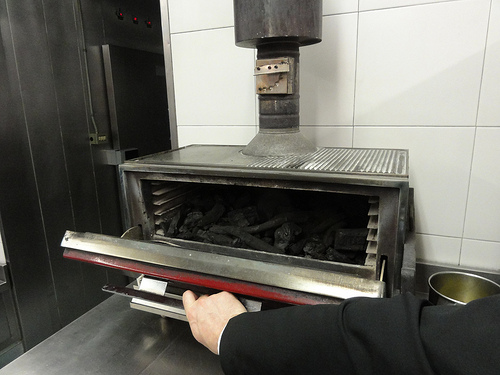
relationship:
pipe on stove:
[233, 2, 322, 157] [61, 143, 414, 323]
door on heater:
[58, 217, 383, 323] [58, 142, 413, 337]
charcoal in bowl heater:
[163, 200, 365, 273] [60, 0, 414, 335]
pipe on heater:
[233, 2, 322, 157] [232, 4, 357, 144]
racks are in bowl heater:
[365, 201, 377, 268] [60, 0, 414, 335]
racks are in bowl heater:
[150, 185, 182, 227] [60, 0, 414, 335]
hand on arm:
[180, 287, 252, 363] [174, 279, 355, 367]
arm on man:
[174, 279, 355, 367] [163, 269, 495, 369]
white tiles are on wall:
[170, 16, 482, 168] [177, 10, 493, 173]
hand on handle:
[174, 274, 274, 363] [120, 273, 264, 338]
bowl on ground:
[426, 270, 498, 304] [118, 313, 158, 364]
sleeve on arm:
[217, 292, 497, 374] [218, 293, 499, 373]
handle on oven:
[101, 279, 261, 325] [57, 142, 419, 336]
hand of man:
[180, 287, 252, 363] [214, 285, 497, 373]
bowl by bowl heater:
[426, 270, 498, 304] [274, 161, 490, 309]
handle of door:
[98, 279, 185, 334] [71, 217, 377, 312]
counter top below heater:
[0, 278, 431, 373] [58, 142, 413, 337]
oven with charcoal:
[57, 142, 419, 336] [216, 210, 306, 234]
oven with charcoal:
[57, 142, 419, 336] [273, 220, 303, 246]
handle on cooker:
[101, 279, 261, 325] [111, 248, 271, 335]